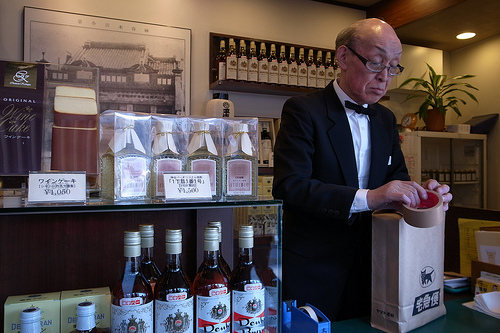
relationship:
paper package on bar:
[368, 209, 446, 331] [331, 278, 498, 331]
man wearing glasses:
[269, 16, 455, 327] [332, 37, 399, 75]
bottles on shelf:
[103, 213, 311, 328] [208, 24, 335, 94]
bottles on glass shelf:
[110, 226, 158, 332] [2, 193, 287, 331]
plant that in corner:
[412, 72, 442, 124] [435, 48, 465, 128]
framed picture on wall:
[23, 5, 198, 125] [3, 2, 458, 294]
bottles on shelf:
[110, 226, 158, 332] [7, 209, 282, 331]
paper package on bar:
[368, 209, 446, 331] [330, 301, 499, 331]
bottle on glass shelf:
[100, 111, 156, 207] [0, 193, 280, 211]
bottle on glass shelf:
[100, 110, 152, 203] [0, 193, 280, 211]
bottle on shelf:
[221, 35, 242, 82] [210, 67, 330, 97]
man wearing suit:
[269, 16, 455, 327] [272, 77, 413, 321]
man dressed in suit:
[279, 20, 455, 320] [277, 87, 410, 312]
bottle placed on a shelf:
[223, 37, 239, 83] [204, 28, 334, 90]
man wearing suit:
[279, 20, 455, 320] [272, 77, 413, 321]